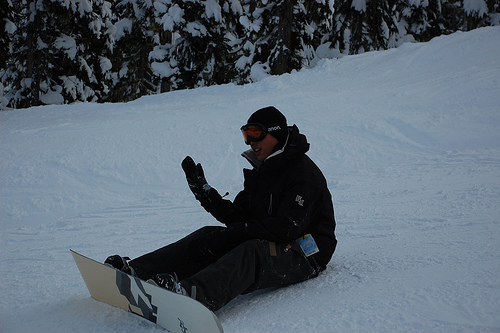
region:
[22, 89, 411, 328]
a person sitting in the snow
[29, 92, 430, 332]
a person sitting in white snow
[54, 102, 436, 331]
a snowboarder on the ground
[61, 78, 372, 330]
a sitting snowboarder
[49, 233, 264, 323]
a gold and white snowboard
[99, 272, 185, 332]
the design on a snowboard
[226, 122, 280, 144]
red snowboard goggles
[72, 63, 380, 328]
an Asian guy snowboarding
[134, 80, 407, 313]
he is in snow gear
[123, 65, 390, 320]
all of his clothes are black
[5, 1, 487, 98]
snow on tree limbs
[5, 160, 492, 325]
packed snow on ground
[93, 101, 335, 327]
snowboarder sitting on ground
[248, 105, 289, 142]
hat on person's head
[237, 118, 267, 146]
goggles with orange lens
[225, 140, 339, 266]
black winter coat on body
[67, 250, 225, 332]
bottom of tilted snowboard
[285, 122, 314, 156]
hood on back of coat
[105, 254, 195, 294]
two boots on snowboard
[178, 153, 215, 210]
mitten on man's hand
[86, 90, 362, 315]
A person that was snowboarding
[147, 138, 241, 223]
They fell on their bum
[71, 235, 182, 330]
The snowboard is white gray and tan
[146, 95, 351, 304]
Wearing a large dark snowsuit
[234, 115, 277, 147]
Large reflective goggles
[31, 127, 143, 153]
The snow is powdery and white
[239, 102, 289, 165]
Wearing a black stocking cap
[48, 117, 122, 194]
The snow is white dust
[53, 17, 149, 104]
The bush has snow on it too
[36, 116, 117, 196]
The snow is dust white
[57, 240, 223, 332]
a colorful snowboard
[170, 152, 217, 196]
a snowboarder is wearing snow gloves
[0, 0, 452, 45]
snow on top of tree branches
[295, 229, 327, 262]
a ski station tag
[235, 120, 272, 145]
an orange wind sunglasses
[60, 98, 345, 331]
a snowboarder is sitting on snow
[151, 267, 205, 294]
part of snowboarder boots.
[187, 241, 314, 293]
a snowboarder is wearing snow pants.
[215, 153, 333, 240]
a black anti wind jacket.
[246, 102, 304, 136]
a man is wearing a black snow hat on top of his head.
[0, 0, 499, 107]
Trees are in the background.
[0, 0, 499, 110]
The trees are green.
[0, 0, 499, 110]
The trees have snow on them.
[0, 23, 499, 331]
Snow is on the ground.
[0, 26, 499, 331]
The snow is white.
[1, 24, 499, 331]
The snow is thick.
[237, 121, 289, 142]
The person is wearing goggles.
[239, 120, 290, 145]
The goggles are black.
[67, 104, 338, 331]
The person is snowboarding.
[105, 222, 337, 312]
The person is wearing black pants.